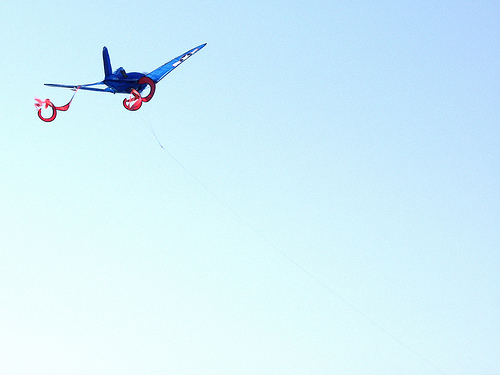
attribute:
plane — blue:
[37, 29, 217, 123]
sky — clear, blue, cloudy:
[276, 62, 326, 108]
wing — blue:
[152, 46, 207, 68]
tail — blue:
[90, 41, 120, 85]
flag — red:
[33, 93, 70, 124]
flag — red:
[116, 93, 155, 113]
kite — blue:
[16, 41, 212, 91]